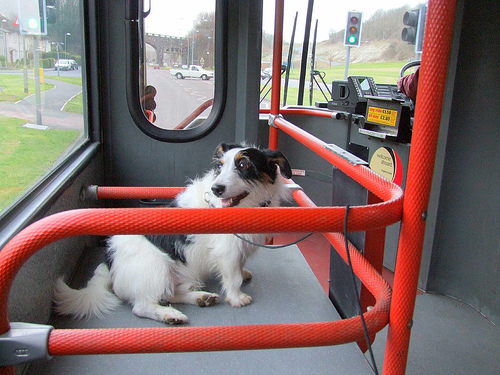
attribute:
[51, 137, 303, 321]
dog — small, brown black white, black, sitting, white, brown, happy, long haired, pretty, little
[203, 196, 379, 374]
leash — black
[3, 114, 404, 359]
handrail — red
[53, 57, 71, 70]
car — parked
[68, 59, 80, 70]
car — parked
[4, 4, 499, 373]
bus — gray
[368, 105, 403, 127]
sticker — yellow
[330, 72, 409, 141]
farebox — metal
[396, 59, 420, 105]
driver — driving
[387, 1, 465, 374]
post — red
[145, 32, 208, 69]
bridge — ahead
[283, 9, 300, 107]
wiper — vertical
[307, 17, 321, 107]
wiper — vertical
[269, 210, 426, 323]
floor — red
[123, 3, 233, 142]
rubber — black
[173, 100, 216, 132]
railing — metal, orange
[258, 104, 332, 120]
railing — orange, metal, red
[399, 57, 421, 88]
steering wheel — black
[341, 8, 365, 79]
traffic light — green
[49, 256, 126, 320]
tail — fluffy, long, white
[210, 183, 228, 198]
nose — black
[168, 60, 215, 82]
truck — long, white, turning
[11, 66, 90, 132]
sidewalk — winding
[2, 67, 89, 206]
grass — green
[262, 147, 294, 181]
ear — black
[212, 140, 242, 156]
ear — black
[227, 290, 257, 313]
paw — white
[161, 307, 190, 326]
paw — white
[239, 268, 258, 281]
paw — white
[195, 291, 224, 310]
paw — white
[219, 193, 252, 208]
mouth — open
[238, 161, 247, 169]
eye — brown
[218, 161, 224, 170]
eye — brown